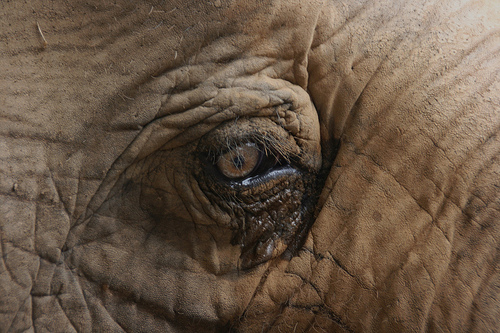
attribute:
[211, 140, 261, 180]
eye — hazel colored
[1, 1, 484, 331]
elephant — big, grey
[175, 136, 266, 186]
eye — yellow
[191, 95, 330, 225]
eye — wet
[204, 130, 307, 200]
eye — brown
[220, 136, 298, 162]
eye lashes — thin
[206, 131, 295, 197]
eye — elephant 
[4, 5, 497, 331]
skin — wrinkled, elephant's, gray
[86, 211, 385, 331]
skin — elephant's, cracked